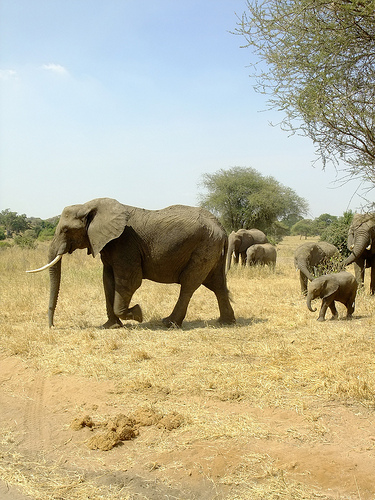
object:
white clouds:
[4, 62, 81, 105]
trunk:
[306, 290, 319, 312]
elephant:
[246, 244, 277, 274]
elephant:
[294, 241, 340, 297]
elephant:
[306, 271, 358, 322]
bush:
[202, 167, 305, 240]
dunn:
[70, 402, 183, 451]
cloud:
[1, 58, 97, 138]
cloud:
[0, 118, 369, 233]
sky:
[0, 16, 372, 224]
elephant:
[25, 196, 237, 331]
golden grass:
[2, 236, 374, 499]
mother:
[225, 227, 266, 270]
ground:
[1, 235, 374, 498]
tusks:
[26, 254, 62, 273]